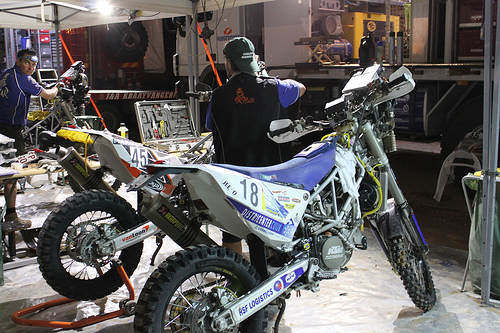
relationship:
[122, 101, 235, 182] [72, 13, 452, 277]
tool box in a garage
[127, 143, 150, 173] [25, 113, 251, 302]
number on bike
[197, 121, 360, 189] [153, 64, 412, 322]
seat on motorcycle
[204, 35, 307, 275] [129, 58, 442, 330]
man near motorcycle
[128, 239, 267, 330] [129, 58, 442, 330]
wheel on motorcycle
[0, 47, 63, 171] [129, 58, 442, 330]
man looking at motorcycle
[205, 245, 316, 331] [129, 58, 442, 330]
chain case for motorcycle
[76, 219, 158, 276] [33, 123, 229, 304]
chain holders on motorcycle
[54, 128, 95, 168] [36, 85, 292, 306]
rope on bike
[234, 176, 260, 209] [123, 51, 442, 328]
number on bike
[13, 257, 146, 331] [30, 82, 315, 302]
bar holding bike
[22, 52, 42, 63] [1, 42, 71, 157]
goggles on man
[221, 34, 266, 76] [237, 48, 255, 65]
hat with letters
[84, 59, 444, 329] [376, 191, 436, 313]
bike has tire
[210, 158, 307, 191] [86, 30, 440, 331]
seat on bike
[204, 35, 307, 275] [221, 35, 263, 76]
man wearing hat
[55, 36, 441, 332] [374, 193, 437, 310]
bike has wheel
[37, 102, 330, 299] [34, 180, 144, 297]
motorcycle has wheel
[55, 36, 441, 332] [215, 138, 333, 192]
bike has seat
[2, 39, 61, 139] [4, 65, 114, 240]
man working on motorcycle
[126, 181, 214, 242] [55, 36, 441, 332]
muffler on bike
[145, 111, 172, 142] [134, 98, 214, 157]
tools are in a tool box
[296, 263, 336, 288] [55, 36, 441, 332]
footrest in a bike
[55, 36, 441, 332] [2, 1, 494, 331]
bike in a shop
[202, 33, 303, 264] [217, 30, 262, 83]
man has cap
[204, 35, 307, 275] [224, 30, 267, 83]
man has cap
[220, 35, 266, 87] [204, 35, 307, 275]
cap on man